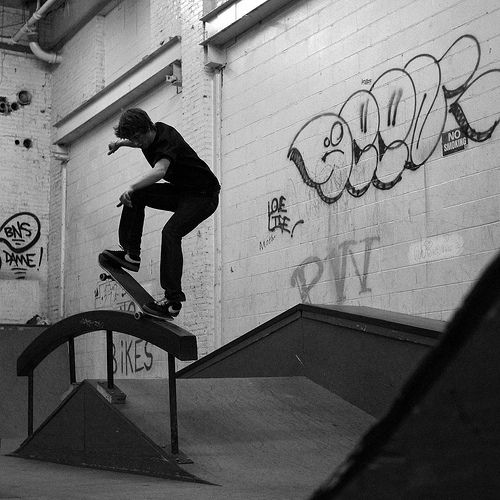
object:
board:
[95, 246, 176, 324]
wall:
[66, 0, 500, 379]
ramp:
[88, 380, 385, 482]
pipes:
[14, 0, 62, 47]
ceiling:
[6, 0, 106, 55]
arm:
[130, 133, 178, 195]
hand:
[116, 187, 134, 209]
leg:
[158, 198, 211, 302]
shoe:
[144, 290, 184, 317]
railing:
[12, 310, 201, 380]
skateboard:
[97, 250, 175, 323]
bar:
[167, 351, 180, 456]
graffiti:
[285, 33, 500, 206]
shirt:
[143, 121, 223, 198]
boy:
[103, 108, 220, 321]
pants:
[118, 177, 222, 295]